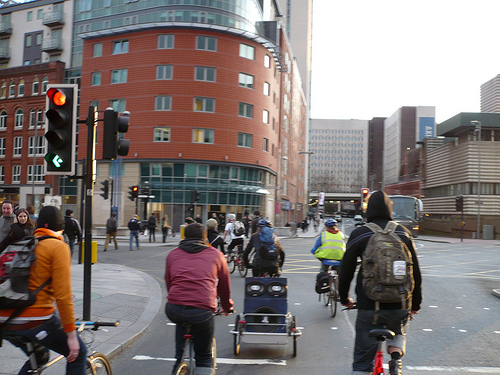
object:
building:
[0, 0, 312, 232]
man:
[337, 189, 422, 374]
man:
[163, 222, 233, 374]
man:
[0, 197, 18, 244]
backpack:
[361, 221, 415, 302]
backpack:
[259, 239, 278, 262]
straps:
[363, 221, 385, 233]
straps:
[32, 276, 52, 293]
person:
[310, 217, 348, 272]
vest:
[313, 229, 347, 258]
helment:
[322, 219, 337, 226]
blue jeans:
[164, 301, 215, 367]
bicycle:
[231, 263, 304, 357]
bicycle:
[341, 301, 395, 375]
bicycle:
[318, 257, 343, 318]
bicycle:
[216, 242, 254, 278]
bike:
[2, 321, 120, 372]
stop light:
[50, 88, 69, 104]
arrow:
[50, 155, 65, 170]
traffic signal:
[43, 83, 74, 178]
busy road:
[0, 217, 500, 373]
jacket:
[164, 239, 233, 311]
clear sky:
[309, 0, 500, 125]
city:
[0, 0, 500, 374]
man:
[0, 206, 88, 374]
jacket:
[0, 228, 77, 334]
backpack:
[0, 236, 52, 325]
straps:
[36, 234, 60, 242]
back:
[29, 237, 48, 288]